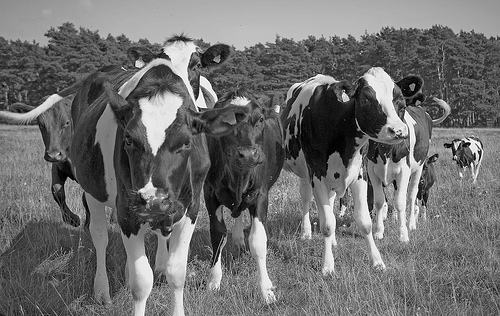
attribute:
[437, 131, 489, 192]
cow — black, white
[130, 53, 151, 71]
tag — white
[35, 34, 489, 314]
cows — grouped, gazing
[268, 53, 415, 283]
cow — two toned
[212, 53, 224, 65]
tag — plastic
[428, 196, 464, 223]
flowers — small, wild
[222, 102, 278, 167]
face — curious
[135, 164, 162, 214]
spot — white 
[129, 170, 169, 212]
nose — cows 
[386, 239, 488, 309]
grass — long leaves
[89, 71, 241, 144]
ears — a pair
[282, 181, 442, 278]
legs — a bunch